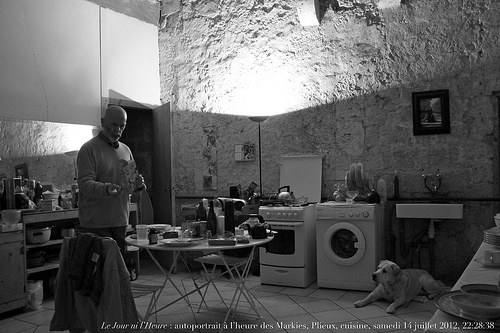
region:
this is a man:
[78, 113, 165, 227]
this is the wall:
[326, 103, 401, 136]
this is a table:
[160, 244, 212, 261]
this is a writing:
[143, 313, 256, 325]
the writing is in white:
[271, 316, 347, 331]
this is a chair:
[78, 241, 145, 315]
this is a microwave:
[266, 204, 309, 277]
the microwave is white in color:
[263, 270, 300, 283]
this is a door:
[151, 102, 177, 164]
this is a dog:
[365, 259, 422, 309]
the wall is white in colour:
[1, 13, 130, 89]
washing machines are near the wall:
[278, 165, 379, 302]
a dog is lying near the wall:
[336, 248, 451, 320]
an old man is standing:
[86, 78, 156, 263]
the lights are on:
[176, 53, 315, 145]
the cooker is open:
[181, 83, 317, 258]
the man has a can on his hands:
[35, 87, 170, 257]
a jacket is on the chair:
[41, 210, 128, 312]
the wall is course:
[255, 73, 397, 140]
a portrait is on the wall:
[395, 70, 460, 141]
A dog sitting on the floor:
[350, 245, 452, 310]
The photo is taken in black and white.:
[48, 38, 493, 306]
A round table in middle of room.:
[128, 211, 272, 326]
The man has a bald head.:
[93, 93, 134, 123]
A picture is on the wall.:
[396, 80, 474, 145]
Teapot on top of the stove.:
[273, 183, 294, 202]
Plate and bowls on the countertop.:
[437, 276, 494, 321]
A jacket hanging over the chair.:
[53, 233, 128, 310]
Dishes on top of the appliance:
[331, 158, 388, 202]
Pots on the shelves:
[29, 220, 85, 282]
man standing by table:
[56, 86, 169, 263]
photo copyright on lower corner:
[93, 320, 497, 332]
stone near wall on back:
[246, 203, 314, 279]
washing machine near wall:
[309, 198, 379, 293]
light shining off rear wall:
[211, 62, 341, 162]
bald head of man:
[85, 88, 141, 138]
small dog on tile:
[357, 247, 449, 321]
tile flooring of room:
[254, 275, 381, 330]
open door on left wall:
[115, 93, 206, 239]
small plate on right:
[423, 275, 490, 325]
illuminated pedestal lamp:
[243, 109, 270, 207]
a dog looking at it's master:
[355, 248, 450, 331]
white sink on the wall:
[391, 191, 467, 251]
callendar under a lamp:
[225, 141, 257, 167]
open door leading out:
[120, 91, 187, 237]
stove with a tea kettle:
[261, 181, 312, 290]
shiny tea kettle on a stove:
[272, 180, 294, 210]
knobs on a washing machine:
[336, 205, 377, 224]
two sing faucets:
[412, 166, 448, 201]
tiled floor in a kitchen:
[272, 288, 328, 331]